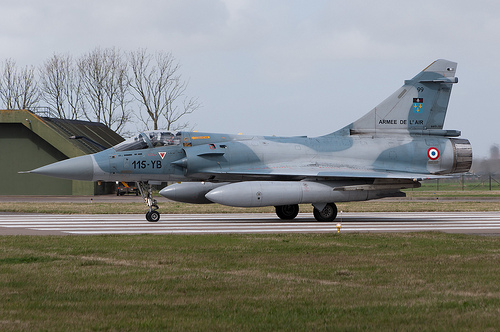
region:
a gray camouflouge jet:
[59, 39, 476, 231]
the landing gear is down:
[126, 181, 344, 233]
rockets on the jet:
[149, 172, 435, 222]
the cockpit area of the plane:
[90, 119, 196, 154]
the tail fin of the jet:
[309, 47, 478, 139]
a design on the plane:
[424, 132, 452, 168]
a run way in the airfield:
[19, 199, 491, 280]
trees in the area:
[14, 58, 182, 108]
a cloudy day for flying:
[139, 19, 362, 107]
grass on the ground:
[32, 241, 439, 317]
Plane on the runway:
[20, 57, 472, 222]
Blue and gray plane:
[19, 58, 476, 223]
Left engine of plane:
[206, 179, 408, 206]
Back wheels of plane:
[272, 204, 339, 220]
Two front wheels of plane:
[146, 203, 160, 223]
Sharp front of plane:
[18, 131, 155, 181]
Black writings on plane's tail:
[378, 116, 428, 125]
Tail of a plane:
[349, 58, 459, 138]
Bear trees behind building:
[1, 47, 189, 129]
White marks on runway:
[1, 210, 499, 233]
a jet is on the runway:
[28, 48, 474, 219]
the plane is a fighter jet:
[23, 58, 473, 225]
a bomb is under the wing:
[208, 180, 407, 207]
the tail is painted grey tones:
[346, 58, 461, 138]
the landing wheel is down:
[143, 187, 162, 222]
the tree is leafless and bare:
[124, 48, 184, 163]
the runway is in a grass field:
[3, 189, 496, 327]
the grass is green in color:
[3, 224, 497, 329]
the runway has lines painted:
[3, 208, 496, 228]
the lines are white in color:
[2, 210, 499, 232]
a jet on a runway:
[41, 68, 472, 225]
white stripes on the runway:
[49, 209, 119, 241]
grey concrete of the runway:
[6, 223, 38, 236]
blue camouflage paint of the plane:
[226, 130, 371, 187]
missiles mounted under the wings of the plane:
[159, 174, 385, 210]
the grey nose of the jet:
[13, 153, 98, 183]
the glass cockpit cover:
[113, 126, 182, 153]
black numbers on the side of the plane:
[125, 157, 167, 172]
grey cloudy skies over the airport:
[222, 0, 317, 96]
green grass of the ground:
[209, 237, 308, 299]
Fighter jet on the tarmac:
[8, 55, 475, 227]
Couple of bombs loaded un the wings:
[154, 173, 425, 210]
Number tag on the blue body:
[128, 157, 166, 172]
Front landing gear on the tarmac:
[133, 177, 161, 224]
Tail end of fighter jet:
[348, 53, 477, 183]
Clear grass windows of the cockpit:
[108, 128, 182, 154]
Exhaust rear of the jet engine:
[443, 129, 475, 179]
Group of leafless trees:
[0, 44, 202, 146]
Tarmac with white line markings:
[0, 209, 499, 239]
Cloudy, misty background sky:
[0, 20, 499, 175]